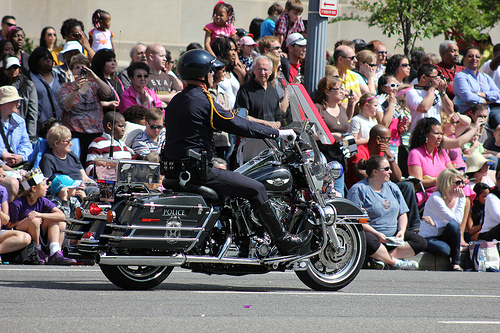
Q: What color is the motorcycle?
A: Black.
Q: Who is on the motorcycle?
A: A Policeman.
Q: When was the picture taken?
A: Daytime.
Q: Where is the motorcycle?
A: The street.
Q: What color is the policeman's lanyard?
A: Yellow.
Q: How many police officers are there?
A: One.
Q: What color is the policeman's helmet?
A: Black.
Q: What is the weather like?
A: Sunny.